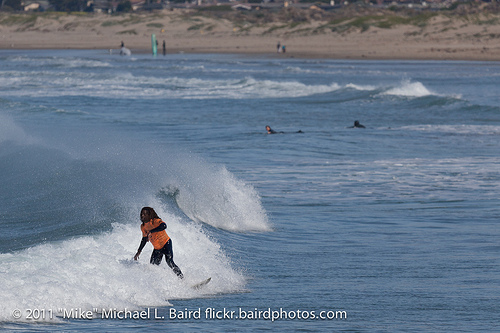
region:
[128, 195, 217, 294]
A man on a surfboard.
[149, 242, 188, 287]
Black wet suit pants.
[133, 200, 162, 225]
A man with dreadlocks.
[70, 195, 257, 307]
A man rides the wave.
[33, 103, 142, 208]
The water splashes in the air.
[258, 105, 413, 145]
People paddle out to sea.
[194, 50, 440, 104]
Waves in the ocean.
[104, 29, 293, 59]
People on the beach.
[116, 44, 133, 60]
A rock in the water.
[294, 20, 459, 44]
grass on the sandy hill.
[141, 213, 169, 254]
an orange shirt on a person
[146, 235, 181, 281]
black pants on a surfer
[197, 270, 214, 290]
a surf board peeking out of the wave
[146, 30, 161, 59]
a green board standing vertical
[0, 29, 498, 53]
a sandy beach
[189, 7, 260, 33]
green grass past the beach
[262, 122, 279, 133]
a head in the water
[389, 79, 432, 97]
the white top of a crashing wave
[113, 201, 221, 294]
a man surfing on the water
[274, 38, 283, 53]
a person on the beach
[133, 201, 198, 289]
male surfer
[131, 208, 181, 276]
male surfer surfing in ocean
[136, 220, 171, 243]
male surfer wearing orange top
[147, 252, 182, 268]
male surfer wearing black wet suit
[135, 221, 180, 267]
male surfer wearing black wet suit and orange shirt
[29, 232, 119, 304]
white and blue waves in ocean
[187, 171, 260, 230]
white and blue waves in ocean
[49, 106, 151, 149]
white and blue waves in ocean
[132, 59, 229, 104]
white and blue waves in ocean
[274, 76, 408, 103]
white and blue waves in ocean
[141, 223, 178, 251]
Her life vest is orange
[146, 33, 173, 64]
the surfboard is a light blue color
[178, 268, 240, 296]
The surfboard is dark and in the water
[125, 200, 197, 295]
the lady is wearing a orange top with black pants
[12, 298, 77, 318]
the photo was taken in 2011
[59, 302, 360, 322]
michael L Baird is the maker of this picture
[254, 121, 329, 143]
person swimming in water pointed left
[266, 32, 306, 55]
people on the beach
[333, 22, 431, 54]
Sandy beach with green areas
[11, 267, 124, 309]
White foamy part of the wave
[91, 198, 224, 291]
man surfing a wave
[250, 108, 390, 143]
two people laying in the water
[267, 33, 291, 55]
people standing on the beach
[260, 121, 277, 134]
head sticking out of the water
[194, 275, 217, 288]
tip of the surfboard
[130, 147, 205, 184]
sprinkles of water coming off the wave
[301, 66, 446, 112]
wave rolling into shore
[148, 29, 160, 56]
sea foam green pole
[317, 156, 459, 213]
small ripples in the water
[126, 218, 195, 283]
black wetsuit under an orange top